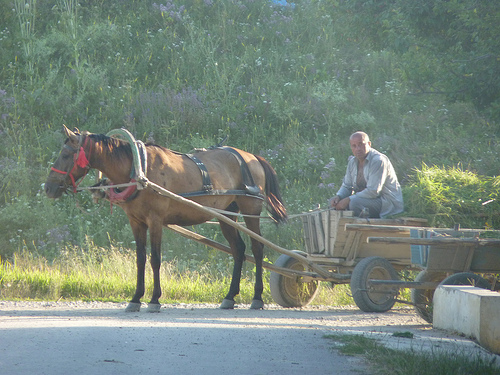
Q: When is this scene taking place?
A: Daytime.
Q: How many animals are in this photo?
A: One.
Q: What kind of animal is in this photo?
A: Horse.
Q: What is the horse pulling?
A: Wooden cart and person.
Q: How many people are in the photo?
A: One.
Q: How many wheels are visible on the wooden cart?
A: Four.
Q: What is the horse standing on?
A: Dirt.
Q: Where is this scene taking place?
A: On a farm.